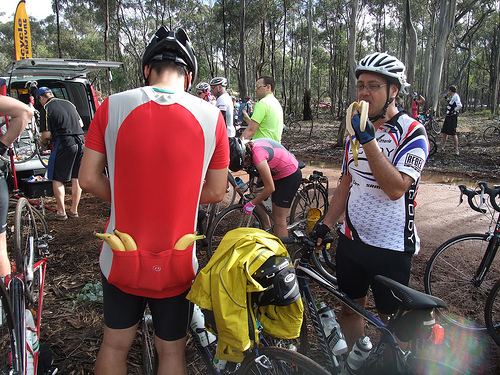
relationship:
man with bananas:
[80, 22, 222, 368] [97, 223, 140, 255]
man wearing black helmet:
[80, 22, 222, 368] [144, 29, 197, 55]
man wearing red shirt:
[80, 22, 222, 368] [96, 92, 220, 252]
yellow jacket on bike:
[214, 267, 239, 305] [304, 275, 450, 370]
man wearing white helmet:
[313, 50, 428, 278] [356, 51, 411, 82]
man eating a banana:
[313, 50, 428, 278] [350, 100, 371, 127]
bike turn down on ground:
[17, 194, 57, 375] [59, 228, 88, 275]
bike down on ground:
[17, 194, 57, 375] [59, 228, 88, 275]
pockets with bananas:
[113, 253, 192, 288] [97, 223, 140, 255]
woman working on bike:
[231, 140, 305, 228] [304, 275, 450, 370]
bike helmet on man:
[304, 275, 450, 370] [80, 22, 222, 368]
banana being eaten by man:
[350, 100, 371, 127] [80, 22, 222, 368]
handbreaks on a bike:
[457, 182, 470, 206] [304, 275, 450, 370]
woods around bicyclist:
[419, 6, 498, 84] [4, 28, 474, 337]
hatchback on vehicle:
[15, 56, 122, 80] [12, 57, 95, 187]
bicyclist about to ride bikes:
[4, 28, 474, 337] [227, 171, 361, 370]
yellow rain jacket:
[214, 267, 239, 305] [208, 236, 295, 348]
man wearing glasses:
[313, 50, 428, 278] [355, 81, 385, 91]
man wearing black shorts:
[80, 22, 222, 368] [99, 296, 190, 341]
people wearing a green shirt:
[235, 73, 284, 145] [255, 100, 282, 138]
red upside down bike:
[36, 261, 44, 268] [17, 194, 57, 375]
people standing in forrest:
[231, 14, 320, 135] [292, 3, 345, 125]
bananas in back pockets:
[97, 223, 140, 255] [113, 253, 192, 288]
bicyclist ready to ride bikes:
[4, 28, 474, 337] [227, 171, 361, 370]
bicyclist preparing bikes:
[4, 28, 474, 337] [227, 171, 361, 370]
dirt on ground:
[427, 200, 450, 228] [59, 228, 88, 275]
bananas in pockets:
[97, 223, 140, 255] [113, 253, 192, 288]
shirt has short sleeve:
[96, 92, 220, 252] [207, 130, 232, 185]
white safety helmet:
[381, 56, 393, 67] [356, 51, 411, 82]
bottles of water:
[317, 300, 374, 372] [320, 303, 346, 353]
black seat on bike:
[410, 292, 429, 304] [304, 275, 450, 370]